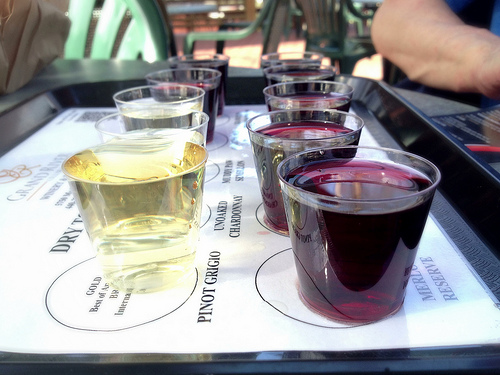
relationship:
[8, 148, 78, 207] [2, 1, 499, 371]
name for wine bar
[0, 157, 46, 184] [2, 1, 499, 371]
logo for wine bar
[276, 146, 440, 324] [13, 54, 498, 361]
glass on table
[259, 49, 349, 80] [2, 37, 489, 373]
glass on table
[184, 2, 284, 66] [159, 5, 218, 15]
chair near table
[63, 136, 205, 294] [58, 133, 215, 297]
white wine in glass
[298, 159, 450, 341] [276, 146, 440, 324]
wine in glass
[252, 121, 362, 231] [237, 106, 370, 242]
wine in glass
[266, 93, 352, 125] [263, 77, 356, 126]
wine in glass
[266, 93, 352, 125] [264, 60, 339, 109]
wine in glass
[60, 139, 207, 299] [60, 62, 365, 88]
glass on a table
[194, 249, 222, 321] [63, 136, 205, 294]
name on white wine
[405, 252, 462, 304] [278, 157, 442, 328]
name next to wine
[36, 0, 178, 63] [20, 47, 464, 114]
chair near table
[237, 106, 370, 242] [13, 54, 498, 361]
glass on top of table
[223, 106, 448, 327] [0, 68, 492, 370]
glass on top of table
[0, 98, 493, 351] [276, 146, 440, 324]
mat under glass